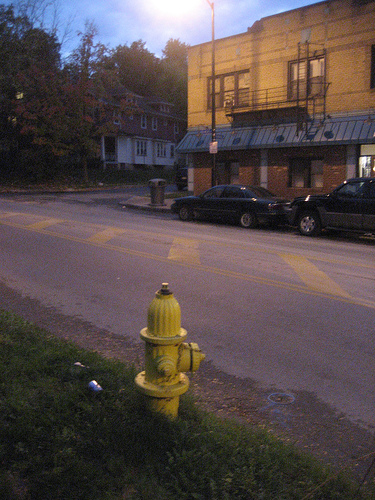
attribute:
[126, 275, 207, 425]
hydrant —  yellow, for fire,  for fire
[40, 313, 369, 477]
leaves —  brown 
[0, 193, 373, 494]
street — damp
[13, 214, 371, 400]
street — asphalt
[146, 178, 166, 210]
can —  for garbage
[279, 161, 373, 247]
truck —  BLACK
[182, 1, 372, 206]
building — two story, brick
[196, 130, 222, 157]
sign — street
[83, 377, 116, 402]
can —  for drink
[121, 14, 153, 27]
sky — clear , blue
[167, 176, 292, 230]
car —  BLACK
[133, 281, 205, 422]
hydrant — yellow, fire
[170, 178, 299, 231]
car —  BLACK